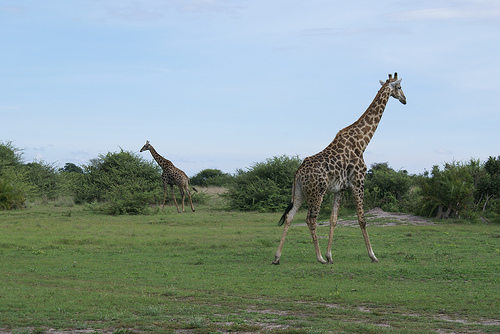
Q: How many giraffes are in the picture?
A: Two.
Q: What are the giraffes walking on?
A: Grass.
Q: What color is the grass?
A: Green.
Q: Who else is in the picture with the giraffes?
A: No one.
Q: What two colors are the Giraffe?
A: Brown and white.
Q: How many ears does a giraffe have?
A: Two.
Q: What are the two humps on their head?
A: Horns.